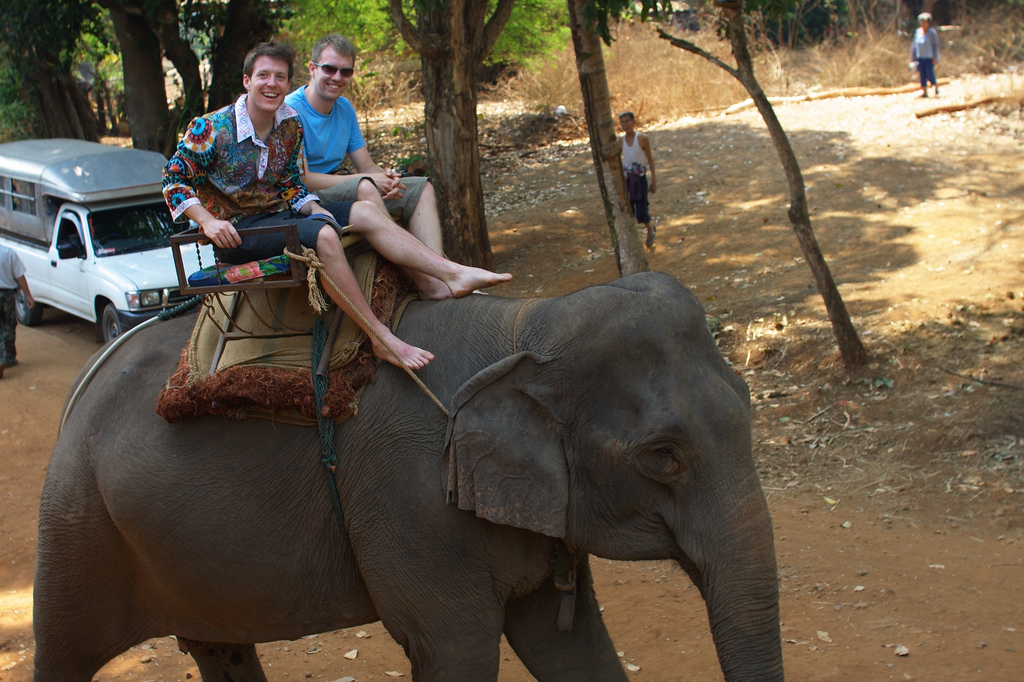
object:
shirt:
[154, 97, 323, 234]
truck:
[0, 128, 243, 357]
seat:
[146, 191, 422, 433]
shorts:
[198, 196, 363, 276]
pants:
[911, 55, 944, 101]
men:
[577, 94, 681, 263]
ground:
[0, 59, 1018, 679]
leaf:
[813, 626, 840, 645]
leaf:
[817, 491, 841, 508]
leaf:
[833, 512, 858, 535]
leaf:
[927, 560, 947, 572]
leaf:
[753, 383, 791, 401]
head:
[231, 36, 301, 117]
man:
[280, 29, 468, 302]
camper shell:
[0, 131, 180, 208]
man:
[135, 34, 514, 373]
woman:
[899, 4, 952, 103]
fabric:
[157, 177, 400, 387]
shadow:
[402, 107, 1021, 432]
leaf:
[335, 645, 367, 662]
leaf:
[375, 666, 402, 679]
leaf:
[614, 652, 653, 676]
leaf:
[874, 629, 920, 664]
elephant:
[12, 246, 791, 682]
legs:
[276, 210, 447, 384]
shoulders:
[174, 100, 253, 147]